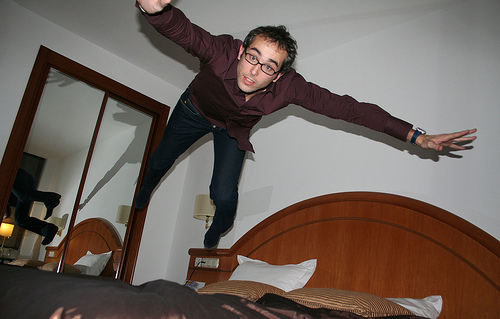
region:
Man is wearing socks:
[126, 185, 223, 255]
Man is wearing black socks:
[130, 186, 223, 251]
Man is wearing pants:
[132, 75, 249, 242]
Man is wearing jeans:
[135, 82, 249, 233]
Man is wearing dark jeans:
[132, 84, 249, 237]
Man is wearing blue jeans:
[135, 82, 245, 239]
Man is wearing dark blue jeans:
[135, 85, 249, 239]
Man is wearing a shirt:
[142, 3, 413, 153]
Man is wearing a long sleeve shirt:
[135, 3, 412, 157]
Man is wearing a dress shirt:
[136, 3, 413, 155]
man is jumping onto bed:
[1, 0, 498, 317]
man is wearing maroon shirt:
[140, 3, 413, 153]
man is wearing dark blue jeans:
[133, 95, 246, 235]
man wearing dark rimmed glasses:
[243, 51, 280, 77]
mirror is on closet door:
[2, 66, 153, 278]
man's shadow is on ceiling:
[20, 0, 451, 89]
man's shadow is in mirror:
[37, 68, 152, 211]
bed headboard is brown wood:
[183, 191, 498, 317]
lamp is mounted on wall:
[192, 193, 216, 228]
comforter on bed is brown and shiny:
[0, 263, 429, 318]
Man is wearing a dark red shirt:
[136, 2, 414, 158]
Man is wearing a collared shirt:
[219, 39, 285, 98]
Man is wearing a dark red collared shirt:
[137, 2, 415, 159]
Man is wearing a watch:
[408, 120, 427, 149]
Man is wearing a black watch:
[411, 123, 427, 149]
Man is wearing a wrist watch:
[407, 124, 426, 147]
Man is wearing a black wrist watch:
[407, 124, 427, 147]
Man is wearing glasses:
[239, 40, 289, 76]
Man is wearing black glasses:
[240, 41, 285, 75]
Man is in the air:
[127, 0, 480, 254]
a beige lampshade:
[193, 187, 213, 217]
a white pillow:
[229, 248, 317, 293]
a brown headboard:
[210, 190, 498, 317]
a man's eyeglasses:
[241, 45, 278, 78]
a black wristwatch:
[410, 126, 424, 144]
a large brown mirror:
[2, 45, 170, 302]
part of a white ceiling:
[30, 0, 457, 95]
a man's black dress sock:
[200, 221, 220, 246]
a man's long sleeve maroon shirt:
[140, 5, 407, 150]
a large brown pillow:
[281, 280, 401, 317]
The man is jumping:
[63, 33, 463, 248]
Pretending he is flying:
[107, 11, 484, 235]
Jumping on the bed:
[66, 225, 456, 312]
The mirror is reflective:
[11, 100, 160, 259]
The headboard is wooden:
[252, 227, 460, 286]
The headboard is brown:
[249, 205, 455, 277]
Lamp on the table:
[182, 193, 227, 257]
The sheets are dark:
[60, 273, 222, 308]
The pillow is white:
[234, 248, 330, 301]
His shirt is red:
[193, 83, 262, 123]